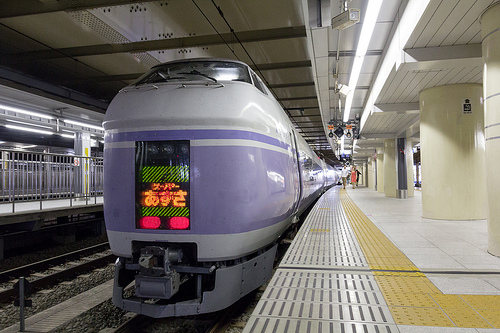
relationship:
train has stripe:
[98, 68, 340, 259] [168, 98, 307, 169]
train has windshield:
[96, 55, 337, 320] [119, 54, 262, 110]